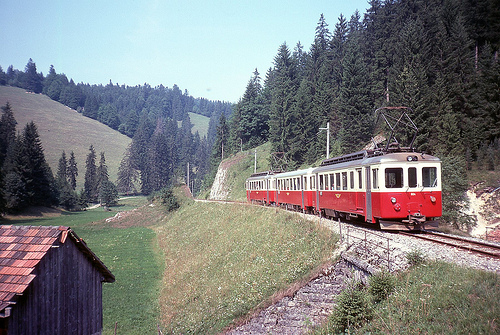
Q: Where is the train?
A: On tracks.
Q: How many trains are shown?
A: One.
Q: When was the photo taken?
A: Daytime.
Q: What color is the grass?
A: Green.